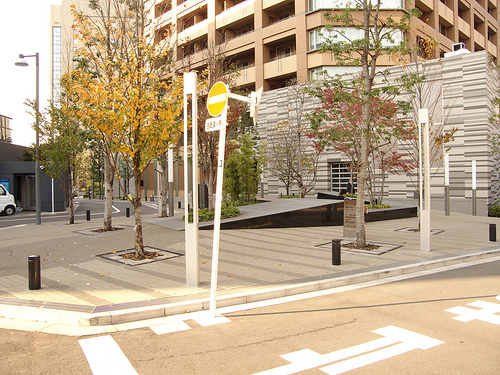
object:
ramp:
[145, 198, 344, 231]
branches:
[426, 123, 443, 147]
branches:
[438, 96, 452, 146]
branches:
[423, 59, 439, 87]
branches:
[400, 139, 419, 154]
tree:
[59, 0, 212, 259]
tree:
[257, 74, 331, 198]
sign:
[205, 116, 222, 133]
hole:
[120, 249, 162, 261]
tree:
[20, 25, 99, 224]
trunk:
[354, 162, 369, 249]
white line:
[442, 295, 499, 326]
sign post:
[207, 108, 227, 310]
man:
[346, 177, 355, 194]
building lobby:
[253, 49, 498, 216]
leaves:
[108, 80, 121, 95]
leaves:
[143, 69, 163, 91]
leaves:
[68, 81, 83, 106]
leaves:
[107, 116, 125, 128]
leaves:
[157, 123, 170, 142]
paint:
[247, 323, 446, 374]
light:
[14, 54, 29, 67]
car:
[0, 182, 17, 215]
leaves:
[33, 147, 63, 180]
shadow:
[0, 214, 499, 294]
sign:
[206, 81, 228, 116]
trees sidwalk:
[59, 25, 219, 261]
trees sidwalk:
[297, 0, 439, 249]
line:
[119, 308, 229, 335]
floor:
[0, 194, 499, 373]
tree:
[221, 130, 266, 207]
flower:
[308, 137, 325, 153]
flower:
[378, 150, 410, 172]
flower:
[323, 86, 336, 101]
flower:
[383, 100, 396, 110]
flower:
[334, 122, 351, 132]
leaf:
[302, 112, 313, 121]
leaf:
[380, 85, 390, 95]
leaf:
[316, 41, 326, 49]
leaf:
[354, 2, 362, 9]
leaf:
[381, 67, 391, 77]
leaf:
[85, 280, 92, 287]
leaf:
[97, 272, 105, 277]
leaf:
[107, 270, 112, 275]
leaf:
[60, 257, 65, 262]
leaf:
[72, 270, 79, 276]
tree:
[187, 29, 252, 211]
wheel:
[4, 204, 16, 216]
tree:
[300, 0, 459, 248]